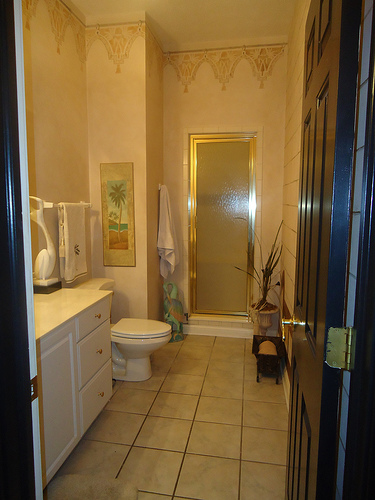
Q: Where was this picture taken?
A: Bathroom.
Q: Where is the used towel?
A: Next to the shower door.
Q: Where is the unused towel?
A: Above the toilet.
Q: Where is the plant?
A: Beside the shower.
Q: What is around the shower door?
A: Gold trim.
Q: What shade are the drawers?
A: White.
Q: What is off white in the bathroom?
A: The tiles.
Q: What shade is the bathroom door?
A: Black.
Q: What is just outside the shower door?
A: A plant.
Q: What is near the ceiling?
A: A border.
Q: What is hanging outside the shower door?
A: A towel.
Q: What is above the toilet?
A: A towel.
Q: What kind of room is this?
A: Bathroom.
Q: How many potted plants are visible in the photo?
A: One.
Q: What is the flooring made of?
A: Tile.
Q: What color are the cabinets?
A: White.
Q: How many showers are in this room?
A: One.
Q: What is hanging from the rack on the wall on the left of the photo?
A: Towel.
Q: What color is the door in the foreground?
A: Black.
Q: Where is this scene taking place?
A: In a bathroom.